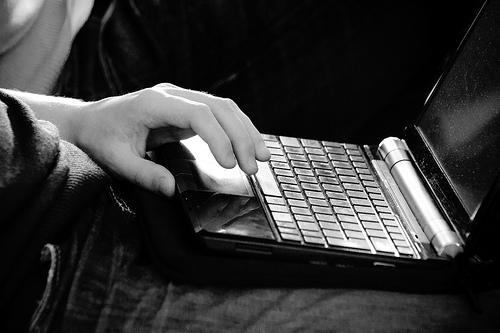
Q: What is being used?
A: A laptop.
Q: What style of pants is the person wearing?
A: Jeans.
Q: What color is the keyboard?
A: Silver.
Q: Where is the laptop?
A: In someone's lap.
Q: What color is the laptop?
A: Black.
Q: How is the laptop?
A: Open.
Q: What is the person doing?
A: Using the laptop mouse.